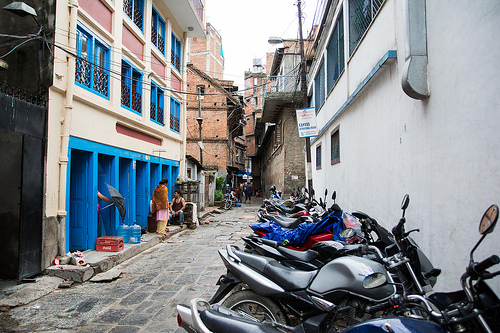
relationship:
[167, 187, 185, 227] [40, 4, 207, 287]
man sitting outside house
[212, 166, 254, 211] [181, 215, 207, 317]
people down street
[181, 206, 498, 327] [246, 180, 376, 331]
motorcycle in line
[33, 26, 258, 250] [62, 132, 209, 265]
building with doors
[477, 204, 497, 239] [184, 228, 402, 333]
mirror on cycle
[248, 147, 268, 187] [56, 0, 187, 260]
opening in wall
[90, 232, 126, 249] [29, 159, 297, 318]
crates on ground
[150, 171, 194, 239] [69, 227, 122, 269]
people on sidewalk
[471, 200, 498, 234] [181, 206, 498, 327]
mirror on motorcycle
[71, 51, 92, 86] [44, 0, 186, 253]
window on building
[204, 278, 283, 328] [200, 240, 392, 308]
tire on motorcycle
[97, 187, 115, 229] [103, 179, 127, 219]
lady with umbrella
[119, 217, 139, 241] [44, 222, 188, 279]
bottles on sidewalk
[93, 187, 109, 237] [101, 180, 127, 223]
lady holding umbrella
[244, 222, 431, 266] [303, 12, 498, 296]
bike in front of wall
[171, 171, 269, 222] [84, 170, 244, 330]
people on street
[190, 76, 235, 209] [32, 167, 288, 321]
post by street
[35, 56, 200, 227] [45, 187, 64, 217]
building without paint